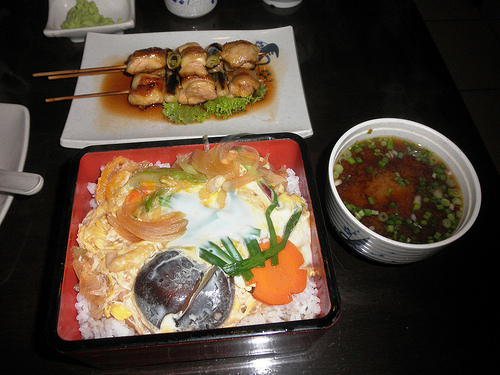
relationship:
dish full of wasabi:
[41, 3, 137, 45] [64, 2, 125, 36]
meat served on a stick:
[122, 47, 170, 75] [28, 49, 271, 78]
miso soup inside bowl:
[332, 134, 465, 245] [321, 114, 482, 268]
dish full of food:
[33, 132, 340, 372] [71, 138, 321, 340]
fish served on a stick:
[179, 43, 211, 79] [28, 49, 271, 78]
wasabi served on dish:
[64, 2, 125, 36] [41, 3, 137, 45]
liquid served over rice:
[160, 182, 314, 271] [74, 160, 322, 346]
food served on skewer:
[131, 74, 170, 109] [44, 78, 266, 110]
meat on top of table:
[122, 47, 170, 75] [0, 0, 498, 374]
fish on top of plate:
[179, 43, 211, 79] [59, 23, 315, 149]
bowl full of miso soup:
[321, 114, 482, 268] [332, 134, 465, 245]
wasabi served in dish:
[64, 2, 125, 36] [41, 3, 137, 45]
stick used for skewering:
[28, 49, 271, 78] [31, 40, 271, 82]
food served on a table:
[71, 138, 321, 340] [0, 0, 498, 374]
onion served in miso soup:
[380, 210, 388, 223] [332, 134, 465, 245]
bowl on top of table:
[321, 114, 482, 268] [0, 0, 498, 374]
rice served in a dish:
[74, 160, 322, 346] [33, 132, 340, 372]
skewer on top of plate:
[44, 78, 266, 110] [59, 23, 315, 149]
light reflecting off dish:
[245, 321, 282, 374] [33, 132, 340, 372]